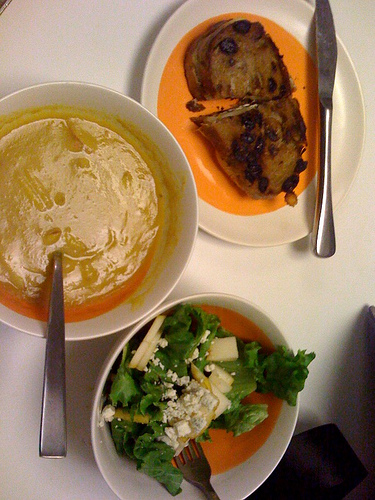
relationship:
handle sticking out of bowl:
[40, 257, 67, 459] [0, 84, 210, 345]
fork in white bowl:
[172, 438, 230, 498] [216, 427, 290, 498]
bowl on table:
[0, 84, 210, 345] [4, 1, 369, 493]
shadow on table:
[27, 274, 324, 499] [4, 1, 369, 493]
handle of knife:
[312, 101, 339, 258] [312, 1, 338, 257]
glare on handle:
[315, 109, 330, 254] [312, 101, 339, 258]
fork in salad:
[173, 438, 219, 500] [127, 304, 300, 492]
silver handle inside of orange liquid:
[38, 255, 68, 459] [69, 289, 108, 309]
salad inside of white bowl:
[101, 302, 316, 497] [91, 289, 313, 498]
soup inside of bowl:
[1, 103, 186, 323] [7, 73, 204, 346]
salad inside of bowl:
[101, 302, 316, 497] [89, 289, 303, 499]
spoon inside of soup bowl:
[38, 250, 69, 459] [1, 80, 202, 341]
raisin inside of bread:
[215, 40, 236, 56] [192, 20, 306, 203]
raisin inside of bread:
[233, 19, 248, 35] [192, 20, 306, 203]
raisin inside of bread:
[238, 135, 251, 143] [192, 20, 306, 203]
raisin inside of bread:
[282, 174, 298, 190] [192, 20, 306, 203]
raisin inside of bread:
[259, 176, 265, 193] [192, 20, 306, 203]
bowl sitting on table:
[89, 289, 303, 499] [4, 1, 369, 493]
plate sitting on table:
[138, 0, 365, 243] [4, 1, 369, 493]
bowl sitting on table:
[0, 82, 198, 341] [4, 1, 369, 493]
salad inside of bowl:
[126, 326, 267, 449] [267, 392, 303, 426]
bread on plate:
[180, 17, 293, 101] [138, 0, 365, 243]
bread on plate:
[189, 95, 307, 204] [138, 0, 365, 243]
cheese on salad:
[161, 365, 225, 448] [94, 316, 312, 491]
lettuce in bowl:
[104, 303, 315, 499] [89, 289, 303, 499]